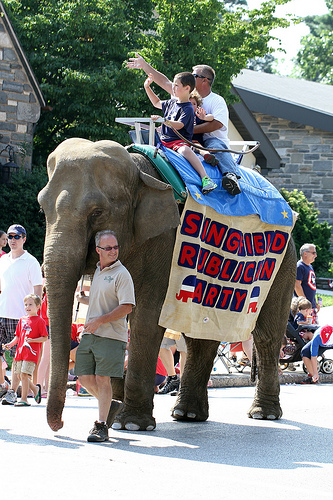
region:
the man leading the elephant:
[79, 223, 134, 444]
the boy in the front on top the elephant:
[136, 65, 212, 192]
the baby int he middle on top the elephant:
[180, 91, 217, 147]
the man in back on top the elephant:
[129, 36, 264, 188]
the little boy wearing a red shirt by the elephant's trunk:
[6, 288, 49, 407]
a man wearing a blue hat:
[0, 215, 51, 394]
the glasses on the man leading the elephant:
[94, 243, 126, 254]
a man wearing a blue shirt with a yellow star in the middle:
[288, 232, 325, 313]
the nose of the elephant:
[36, 245, 78, 440]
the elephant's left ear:
[124, 157, 186, 260]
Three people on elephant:
[118, 47, 292, 194]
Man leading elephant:
[59, 232, 152, 435]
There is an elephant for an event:
[11, 101, 301, 436]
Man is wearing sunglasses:
[58, 215, 130, 277]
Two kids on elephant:
[138, 75, 214, 174]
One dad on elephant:
[185, 60, 241, 186]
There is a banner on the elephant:
[150, 164, 290, 348]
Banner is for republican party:
[169, 172, 287, 327]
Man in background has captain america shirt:
[294, 257, 331, 313]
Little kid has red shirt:
[7, 309, 55, 366]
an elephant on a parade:
[25, 129, 305, 448]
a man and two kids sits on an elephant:
[118, 47, 257, 199]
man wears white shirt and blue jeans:
[186, 51, 256, 191]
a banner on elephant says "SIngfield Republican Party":
[155, 193, 298, 354]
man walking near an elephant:
[66, 226, 141, 445]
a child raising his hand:
[184, 90, 217, 129]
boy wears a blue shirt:
[142, 62, 220, 199]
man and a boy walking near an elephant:
[2, 216, 53, 418]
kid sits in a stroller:
[290, 294, 332, 382]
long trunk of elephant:
[31, 232, 82, 442]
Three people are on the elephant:
[102, 47, 277, 188]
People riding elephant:
[110, 39, 261, 201]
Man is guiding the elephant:
[39, 215, 149, 457]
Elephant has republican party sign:
[4, 118, 330, 459]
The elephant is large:
[27, 114, 306, 451]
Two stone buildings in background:
[1, 9, 331, 268]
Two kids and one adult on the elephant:
[130, 45, 251, 183]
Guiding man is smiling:
[47, 230, 141, 371]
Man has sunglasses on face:
[78, 233, 124, 289]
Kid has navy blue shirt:
[140, 75, 218, 172]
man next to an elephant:
[59, 227, 132, 451]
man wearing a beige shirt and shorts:
[82, 229, 121, 449]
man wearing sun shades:
[79, 221, 150, 447]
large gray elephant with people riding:
[38, 143, 293, 417]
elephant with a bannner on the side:
[29, 130, 315, 391]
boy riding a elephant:
[135, 52, 203, 203]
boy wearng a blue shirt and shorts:
[161, 66, 209, 192]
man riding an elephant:
[193, 57, 224, 155]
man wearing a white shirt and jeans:
[201, 58, 224, 161]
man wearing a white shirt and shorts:
[5, 217, 39, 333]